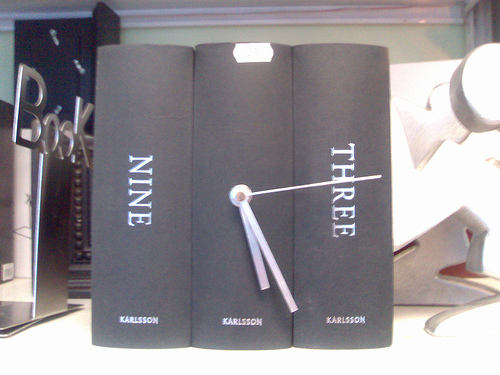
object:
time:
[227, 173, 381, 311]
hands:
[237, 206, 269, 290]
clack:
[227, 175, 380, 312]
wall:
[393, 27, 460, 61]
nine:
[128, 155, 153, 227]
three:
[330, 143, 355, 237]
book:
[91, 46, 193, 346]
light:
[232, 43, 273, 63]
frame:
[11, 64, 96, 170]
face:
[95, 45, 394, 348]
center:
[228, 184, 252, 206]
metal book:
[92, 44, 192, 349]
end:
[293, 42, 388, 64]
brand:
[326, 315, 365, 325]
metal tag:
[222, 318, 262, 326]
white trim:
[390, 60, 426, 107]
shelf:
[0, 298, 499, 375]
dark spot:
[97, 47, 119, 64]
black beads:
[119, 316, 158, 324]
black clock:
[91, 43, 393, 345]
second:
[249, 175, 384, 196]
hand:
[241, 203, 298, 313]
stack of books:
[96, 43, 394, 349]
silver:
[449, 43, 500, 132]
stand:
[393, 206, 500, 336]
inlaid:
[332, 143, 355, 238]